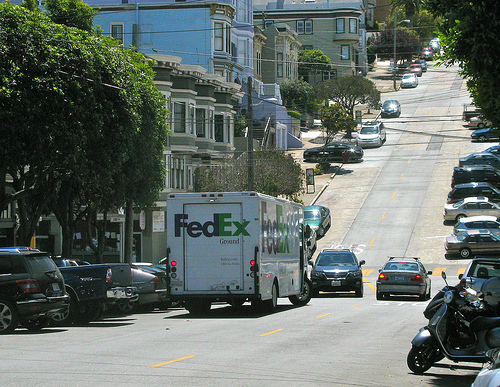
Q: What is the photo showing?
A: It is showing a street.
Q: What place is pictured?
A: It is a street.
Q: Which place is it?
A: It is a street.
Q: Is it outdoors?
A: Yes, it is outdoors.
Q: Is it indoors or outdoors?
A: It is outdoors.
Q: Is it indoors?
A: No, it is outdoors.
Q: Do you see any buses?
A: No, there are no buses.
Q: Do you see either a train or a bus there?
A: No, there are no buses or trains.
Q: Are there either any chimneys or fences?
A: No, there are no fences or chimneys.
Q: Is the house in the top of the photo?
A: Yes, the house is in the top of the image.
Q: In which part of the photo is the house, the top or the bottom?
A: The house is in the top of the image.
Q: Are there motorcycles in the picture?
A: Yes, there is a motorcycle.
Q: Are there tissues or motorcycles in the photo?
A: Yes, there is a motorcycle.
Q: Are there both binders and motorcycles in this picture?
A: No, there is a motorcycle but no binders.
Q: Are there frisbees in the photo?
A: No, there are no frisbees.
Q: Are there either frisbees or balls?
A: No, there are no frisbees or balls.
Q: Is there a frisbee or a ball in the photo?
A: No, there are no frisbees or balls.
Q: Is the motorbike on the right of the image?
A: Yes, the motorbike is on the right of the image.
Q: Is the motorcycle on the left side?
A: No, the motorcycle is on the right of the image.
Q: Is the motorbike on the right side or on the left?
A: The motorbike is on the right of the image.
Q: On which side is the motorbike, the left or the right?
A: The motorbike is on the right of the image.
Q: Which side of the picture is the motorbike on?
A: The motorbike is on the right of the image.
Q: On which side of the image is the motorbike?
A: The motorbike is on the right of the image.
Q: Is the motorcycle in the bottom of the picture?
A: Yes, the motorcycle is in the bottom of the image.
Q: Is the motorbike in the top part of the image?
A: No, the motorbike is in the bottom of the image.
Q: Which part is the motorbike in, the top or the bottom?
A: The motorbike is in the bottom of the image.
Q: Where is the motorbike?
A: The motorbike is on the street.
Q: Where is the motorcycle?
A: The motorbike is on the street.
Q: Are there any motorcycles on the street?
A: Yes, there is a motorcycle on the street.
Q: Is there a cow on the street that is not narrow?
A: No, there is a motorcycle on the street.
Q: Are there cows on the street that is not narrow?
A: No, there is a motorcycle on the street.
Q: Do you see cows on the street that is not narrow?
A: No, there is a motorcycle on the street.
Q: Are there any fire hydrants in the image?
A: No, there are no fire hydrants.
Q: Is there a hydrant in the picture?
A: No, there are no fire hydrants.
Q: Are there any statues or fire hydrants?
A: No, there are no fire hydrants or statues.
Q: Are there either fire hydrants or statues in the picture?
A: No, there are no fire hydrants or statues.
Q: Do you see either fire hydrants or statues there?
A: No, there are no fire hydrants or statues.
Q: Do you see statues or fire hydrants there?
A: No, there are no fire hydrants or statues.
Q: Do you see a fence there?
A: No, there are no fences.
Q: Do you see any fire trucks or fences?
A: No, there are no fences or fire trucks.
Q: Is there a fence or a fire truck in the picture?
A: No, there are no fences or fire trucks.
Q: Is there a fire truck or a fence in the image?
A: No, there are no fences or fire trucks.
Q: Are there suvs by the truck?
A: Yes, there is a SUV by the truck.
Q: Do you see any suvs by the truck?
A: Yes, there is a SUV by the truck.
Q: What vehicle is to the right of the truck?
A: The vehicle is a SUV.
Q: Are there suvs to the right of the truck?
A: Yes, there is a SUV to the right of the truck.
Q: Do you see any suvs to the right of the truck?
A: Yes, there is a SUV to the right of the truck.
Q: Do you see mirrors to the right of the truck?
A: No, there is a SUV to the right of the truck.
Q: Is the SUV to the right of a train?
A: No, the SUV is to the right of the truck.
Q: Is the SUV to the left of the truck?
A: No, the SUV is to the right of the truck.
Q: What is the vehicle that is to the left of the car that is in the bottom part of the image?
A: The vehicle is a SUV.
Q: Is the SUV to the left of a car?
A: Yes, the SUV is to the left of a car.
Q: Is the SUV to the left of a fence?
A: No, the SUV is to the left of a car.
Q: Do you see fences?
A: No, there are no fences.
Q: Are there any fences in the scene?
A: No, there are no fences.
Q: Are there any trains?
A: No, there are no trains.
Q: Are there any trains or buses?
A: No, there are no trains or buses.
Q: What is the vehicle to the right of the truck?
A: The vehicle is a car.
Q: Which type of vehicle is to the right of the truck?
A: The vehicle is a car.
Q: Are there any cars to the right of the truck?
A: Yes, there is a car to the right of the truck.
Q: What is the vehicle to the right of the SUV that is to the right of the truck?
A: The vehicle is a car.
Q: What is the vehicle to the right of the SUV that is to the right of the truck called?
A: The vehicle is a car.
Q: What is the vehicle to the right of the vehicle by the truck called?
A: The vehicle is a car.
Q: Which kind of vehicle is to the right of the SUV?
A: The vehicle is a car.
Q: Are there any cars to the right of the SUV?
A: Yes, there is a car to the right of the SUV.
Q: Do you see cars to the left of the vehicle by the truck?
A: No, the car is to the right of the SUV.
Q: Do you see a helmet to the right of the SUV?
A: No, there is a car to the right of the SUV.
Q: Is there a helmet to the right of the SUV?
A: No, there is a car to the right of the SUV.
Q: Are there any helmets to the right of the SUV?
A: No, there is a car to the right of the SUV.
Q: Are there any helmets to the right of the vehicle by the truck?
A: No, there is a car to the right of the SUV.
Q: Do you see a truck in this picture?
A: Yes, there is a truck.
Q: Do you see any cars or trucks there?
A: Yes, there is a truck.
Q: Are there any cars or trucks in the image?
A: Yes, there is a truck.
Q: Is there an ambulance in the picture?
A: No, there are no ambulances.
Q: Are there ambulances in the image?
A: No, there are no ambulances.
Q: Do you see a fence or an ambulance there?
A: No, there are no ambulances or fences.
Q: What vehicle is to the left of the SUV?
A: The vehicle is a truck.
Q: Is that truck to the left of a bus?
A: No, the truck is to the left of the SUV.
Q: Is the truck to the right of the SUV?
A: No, the truck is to the left of the SUV.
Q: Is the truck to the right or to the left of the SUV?
A: The truck is to the left of the SUV.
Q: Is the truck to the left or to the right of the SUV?
A: The truck is to the left of the SUV.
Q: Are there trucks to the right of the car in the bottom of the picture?
A: No, the truck is to the left of the car.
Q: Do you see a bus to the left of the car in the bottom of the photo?
A: No, there is a truck to the left of the car.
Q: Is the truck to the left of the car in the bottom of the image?
A: Yes, the truck is to the left of the car.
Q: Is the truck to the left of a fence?
A: No, the truck is to the left of the car.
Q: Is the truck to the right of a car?
A: No, the truck is to the left of a car.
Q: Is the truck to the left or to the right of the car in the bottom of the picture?
A: The truck is to the left of the car.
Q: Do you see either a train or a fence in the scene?
A: No, there are no trains or fences.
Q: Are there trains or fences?
A: No, there are no trains or fences.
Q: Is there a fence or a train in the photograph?
A: No, there are no trains or fences.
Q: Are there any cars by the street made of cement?
A: Yes, there is a car by the street.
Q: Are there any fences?
A: No, there are no fences.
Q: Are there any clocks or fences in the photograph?
A: No, there are no fences or clocks.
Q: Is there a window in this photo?
A: Yes, there is a window.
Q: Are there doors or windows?
A: Yes, there is a window.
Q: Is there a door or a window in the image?
A: Yes, there is a window.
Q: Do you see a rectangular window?
A: Yes, there is a rectangular window.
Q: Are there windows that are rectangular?
A: Yes, there is a window that is rectangular.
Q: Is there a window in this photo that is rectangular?
A: Yes, there is a window that is rectangular.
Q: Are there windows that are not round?
A: Yes, there is a rectangular window.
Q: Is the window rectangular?
A: Yes, the window is rectangular.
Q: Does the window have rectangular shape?
A: Yes, the window is rectangular.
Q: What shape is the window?
A: The window is rectangular.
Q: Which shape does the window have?
A: The window has rectangular shape.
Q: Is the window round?
A: No, the window is rectangular.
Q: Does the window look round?
A: No, the window is rectangular.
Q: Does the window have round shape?
A: No, the window is rectangular.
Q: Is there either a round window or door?
A: No, there is a window but it is rectangular.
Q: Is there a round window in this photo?
A: No, there is a window but it is rectangular.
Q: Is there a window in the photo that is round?
A: No, there is a window but it is rectangular.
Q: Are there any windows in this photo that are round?
A: No, there is a window but it is rectangular.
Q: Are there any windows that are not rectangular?
A: No, there is a window but it is rectangular.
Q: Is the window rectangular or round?
A: The window is rectangular.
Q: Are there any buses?
A: No, there are no buses.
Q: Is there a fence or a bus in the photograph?
A: No, there are no buses or fences.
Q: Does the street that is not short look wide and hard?
A: Yes, the street is wide and hard.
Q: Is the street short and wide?
A: No, the street is wide but long.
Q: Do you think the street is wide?
A: Yes, the street is wide.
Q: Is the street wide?
A: Yes, the street is wide.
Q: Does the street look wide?
A: Yes, the street is wide.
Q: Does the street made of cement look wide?
A: Yes, the street is wide.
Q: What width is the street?
A: The street is wide.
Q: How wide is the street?
A: The street is wide.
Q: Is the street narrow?
A: No, the street is wide.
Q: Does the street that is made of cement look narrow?
A: No, the street is wide.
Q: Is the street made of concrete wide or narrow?
A: The street is wide.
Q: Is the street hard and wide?
A: Yes, the street is hard and wide.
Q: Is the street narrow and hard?
A: No, the street is hard but wide.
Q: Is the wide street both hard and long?
A: Yes, the street is hard and long.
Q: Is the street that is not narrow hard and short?
A: No, the street is hard but long.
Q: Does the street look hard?
A: Yes, the street is hard.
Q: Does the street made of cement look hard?
A: Yes, the street is hard.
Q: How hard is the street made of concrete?
A: The street is hard.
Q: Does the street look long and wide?
A: Yes, the street is long and wide.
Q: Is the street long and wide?
A: Yes, the street is long and wide.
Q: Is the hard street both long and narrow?
A: No, the street is long but wide.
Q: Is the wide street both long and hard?
A: Yes, the street is long and hard.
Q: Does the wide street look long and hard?
A: Yes, the street is long and hard.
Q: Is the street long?
A: Yes, the street is long.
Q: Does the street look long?
A: Yes, the street is long.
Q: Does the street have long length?
A: Yes, the street is long.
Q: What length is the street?
A: The street is long.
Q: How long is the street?
A: The street is long.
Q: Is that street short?
A: No, the street is long.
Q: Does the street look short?
A: No, the street is long.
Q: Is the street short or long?
A: The street is long.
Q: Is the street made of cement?
A: Yes, the street is made of cement.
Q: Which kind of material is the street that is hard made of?
A: The street is made of cement.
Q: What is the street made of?
A: The street is made of concrete.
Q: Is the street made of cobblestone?
A: No, the street is made of concrete.